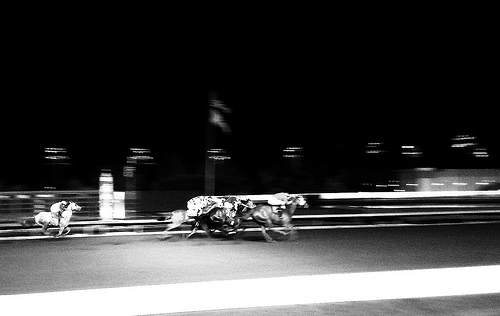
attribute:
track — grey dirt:
[0, 215, 499, 314]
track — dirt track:
[6, 202, 496, 308]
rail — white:
[108, 266, 463, 303]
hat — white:
[64, 200, 69, 205]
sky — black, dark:
[20, 53, 495, 150]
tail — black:
[13, 213, 35, 229]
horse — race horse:
[24, 201, 80, 238]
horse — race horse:
[251, 190, 310, 240]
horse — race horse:
[162, 192, 252, 236]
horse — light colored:
[38, 184, 99, 243]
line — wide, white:
[3, 262, 498, 312]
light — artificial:
[152, 198, 325, 258]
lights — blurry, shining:
[372, 131, 487, 157]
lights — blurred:
[3, 94, 499, 222]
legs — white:
[254, 223, 296, 243]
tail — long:
[12, 214, 37, 232]